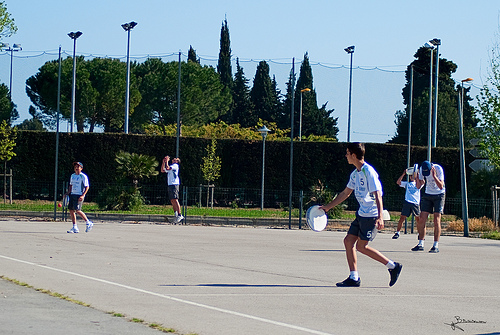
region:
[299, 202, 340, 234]
white Frisbee in man's hand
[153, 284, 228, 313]
solid white line on play ground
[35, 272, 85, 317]
small amount of green grass on side of playground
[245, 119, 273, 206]
long silver pole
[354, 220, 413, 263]
white number on black shorts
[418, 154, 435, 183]
blue cap on man's head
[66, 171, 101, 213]
man wearing white tee shirt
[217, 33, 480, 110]
clear netting above trees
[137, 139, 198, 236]
man jumping in the air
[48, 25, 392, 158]
large cluster of trees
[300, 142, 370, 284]
this is a man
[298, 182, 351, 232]
his hand is holding a plate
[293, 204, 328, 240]
the plate is white in color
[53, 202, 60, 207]
this is a ball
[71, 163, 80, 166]
the boy is wearing a cap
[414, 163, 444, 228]
the man is looking downwards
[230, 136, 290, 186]
the fence is well trimmed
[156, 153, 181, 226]
the player is up on air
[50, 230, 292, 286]
the pitch is tarmacked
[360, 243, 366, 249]
the man is light skinned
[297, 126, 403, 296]
Boy plays freesbee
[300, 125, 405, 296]
Boy in position to trow a freesbee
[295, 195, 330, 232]
Freesbee is white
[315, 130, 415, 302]
Boy has number 5 in front of t-shirt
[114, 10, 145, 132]
Light pole behind a fence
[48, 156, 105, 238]
Person wears cap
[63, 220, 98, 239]
White socks and shoes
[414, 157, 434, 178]
Blue cap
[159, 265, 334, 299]
Shadow of person cast in the ground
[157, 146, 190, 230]
Person jumping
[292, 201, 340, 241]
the Frisbee is white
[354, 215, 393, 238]
his shorts are blue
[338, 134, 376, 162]
his hair is brown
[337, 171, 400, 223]
his shirt is white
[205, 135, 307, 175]
the bush is green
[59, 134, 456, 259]
there are five players in the court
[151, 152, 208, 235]
the player is in the air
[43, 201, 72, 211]
the ball is in the air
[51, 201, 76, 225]
the ball is orange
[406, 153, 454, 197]
his hat is blue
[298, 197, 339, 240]
A white frisbee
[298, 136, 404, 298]
A boy prepares to throw a frisbee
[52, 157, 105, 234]
A boy with a white shirt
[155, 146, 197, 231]
A man jumps in the air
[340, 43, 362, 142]
A light pole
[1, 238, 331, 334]
A concrete surface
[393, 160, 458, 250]
Two people wait their turn for frisbee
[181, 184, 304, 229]
A metal fence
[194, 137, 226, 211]
A small sapling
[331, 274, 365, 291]
Black sneaker